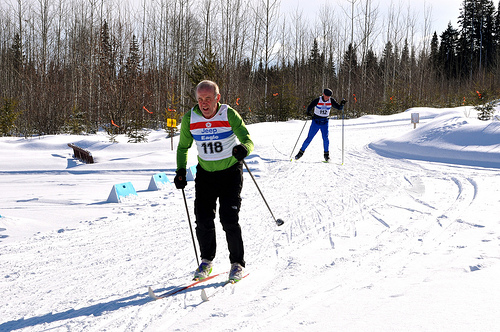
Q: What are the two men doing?
A: Skiing.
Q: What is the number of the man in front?
A: One hundred eighteen.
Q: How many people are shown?
A: 2.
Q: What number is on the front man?
A: 118.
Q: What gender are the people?
A: Male.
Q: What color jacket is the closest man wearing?
A: Green.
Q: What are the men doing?
A: Skiing.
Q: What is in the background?
A: Trees.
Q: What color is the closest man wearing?
A: Black.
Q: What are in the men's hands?
A: Ski poles.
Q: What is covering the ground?
A: Snow.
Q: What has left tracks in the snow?
A: Skis.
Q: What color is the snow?
A: White.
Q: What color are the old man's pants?
A: Black.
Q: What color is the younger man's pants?
A: Blue.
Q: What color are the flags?
A: Orange.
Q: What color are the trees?
A: Brown.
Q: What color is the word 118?
A: Black.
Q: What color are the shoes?
A: White.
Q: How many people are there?
A: 2.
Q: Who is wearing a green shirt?
A: Skier number 118.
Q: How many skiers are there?
A: 2.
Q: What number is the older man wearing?
A: 118.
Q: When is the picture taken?
A: Daytime.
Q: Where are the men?
A: On a ski slope.